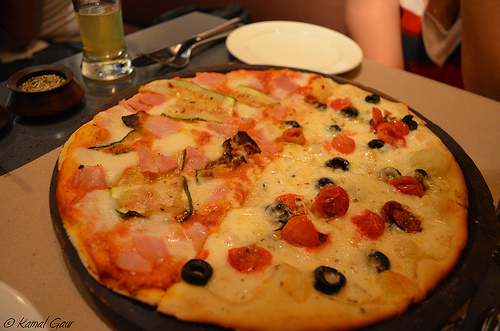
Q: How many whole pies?
A: One.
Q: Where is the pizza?
A: On the tray.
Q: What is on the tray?
A: Pizza.